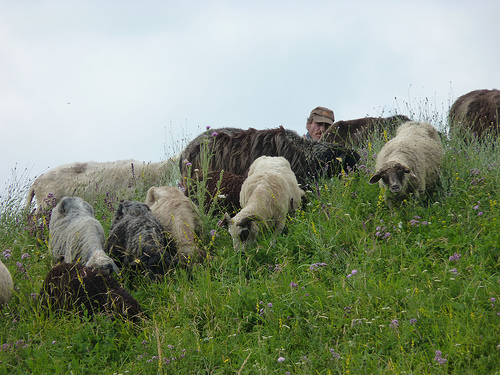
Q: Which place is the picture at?
A: It is at the pasture.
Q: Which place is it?
A: It is a pasture.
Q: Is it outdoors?
A: Yes, it is outdoors.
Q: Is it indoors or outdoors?
A: It is outdoors.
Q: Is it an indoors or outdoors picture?
A: It is outdoors.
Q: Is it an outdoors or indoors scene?
A: It is outdoors.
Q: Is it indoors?
A: No, it is outdoors.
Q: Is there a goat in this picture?
A: Yes, there is a goat.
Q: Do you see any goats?
A: Yes, there is a goat.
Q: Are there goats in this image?
A: Yes, there is a goat.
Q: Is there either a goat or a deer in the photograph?
A: Yes, there is a goat.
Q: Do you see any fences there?
A: No, there are no fences.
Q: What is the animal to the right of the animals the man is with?
A: The animal is a goat.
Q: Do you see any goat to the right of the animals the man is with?
A: Yes, there is a goat to the right of the animals.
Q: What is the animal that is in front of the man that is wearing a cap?
A: The animal is a goat.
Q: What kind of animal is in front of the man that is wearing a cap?
A: The animal is a goat.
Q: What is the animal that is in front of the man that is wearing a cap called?
A: The animal is a goat.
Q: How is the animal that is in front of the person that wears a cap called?
A: The animal is a goat.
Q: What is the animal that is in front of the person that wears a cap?
A: The animal is a goat.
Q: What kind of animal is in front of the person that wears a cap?
A: The animal is a goat.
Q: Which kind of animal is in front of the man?
A: The animal is a goat.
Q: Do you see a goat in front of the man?
A: Yes, there is a goat in front of the man.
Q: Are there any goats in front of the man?
A: Yes, there is a goat in front of the man.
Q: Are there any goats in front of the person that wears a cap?
A: Yes, there is a goat in front of the man.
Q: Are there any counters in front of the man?
A: No, there is a goat in front of the man.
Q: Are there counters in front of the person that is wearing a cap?
A: No, there is a goat in front of the man.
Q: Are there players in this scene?
A: No, there are no players.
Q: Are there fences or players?
A: No, there are no players or fences.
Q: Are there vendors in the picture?
A: No, there are no vendors.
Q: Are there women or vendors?
A: No, there are no vendors or women.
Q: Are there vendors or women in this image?
A: No, there are no vendors or women.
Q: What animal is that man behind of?
A: The man is behind the goat.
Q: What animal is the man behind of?
A: The man is behind the goat.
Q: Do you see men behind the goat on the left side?
A: Yes, there is a man behind the goat.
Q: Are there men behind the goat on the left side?
A: Yes, there is a man behind the goat.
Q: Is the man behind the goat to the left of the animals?
A: Yes, the man is behind the goat.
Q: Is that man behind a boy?
A: No, the man is behind the goat.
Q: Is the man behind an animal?
A: Yes, the man is behind an animal.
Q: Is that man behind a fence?
A: No, the man is behind an animal.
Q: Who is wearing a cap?
A: The man is wearing a cap.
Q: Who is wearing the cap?
A: The man is wearing a cap.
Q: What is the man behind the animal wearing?
A: The man is wearing a cap.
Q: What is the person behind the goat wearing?
A: The man is wearing a cap.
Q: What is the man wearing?
A: The man is wearing a cap.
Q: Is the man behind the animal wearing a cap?
A: Yes, the man is wearing a cap.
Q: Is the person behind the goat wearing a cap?
A: Yes, the man is wearing a cap.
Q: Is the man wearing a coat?
A: No, the man is wearing a cap.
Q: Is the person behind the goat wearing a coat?
A: No, the man is wearing a cap.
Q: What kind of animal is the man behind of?
A: The man is behind the goat.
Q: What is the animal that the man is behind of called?
A: The animal is a goat.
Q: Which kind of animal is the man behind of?
A: The man is behind the goat.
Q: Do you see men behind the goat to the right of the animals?
A: Yes, there is a man behind the goat.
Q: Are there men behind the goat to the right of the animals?
A: Yes, there is a man behind the goat.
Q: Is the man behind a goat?
A: Yes, the man is behind a goat.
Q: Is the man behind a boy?
A: No, the man is behind a goat.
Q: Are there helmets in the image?
A: No, there are no helmets.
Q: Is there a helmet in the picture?
A: No, there are no helmets.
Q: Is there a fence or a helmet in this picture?
A: No, there are no helmets or fences.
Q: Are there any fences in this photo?
A: No, there are no fences.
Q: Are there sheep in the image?
A: Yes, there is a sheep.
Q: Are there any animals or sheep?
A: Yes, there is a sheep.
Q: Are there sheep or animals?
A: Yes, there is a sheep.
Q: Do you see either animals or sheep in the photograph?
A: Yes, there is a sheep.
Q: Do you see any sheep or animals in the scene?
A: Yes, there is a sheep.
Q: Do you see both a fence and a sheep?
A: No, there is a sheep but no fences.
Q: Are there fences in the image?
A: No, there are no fences.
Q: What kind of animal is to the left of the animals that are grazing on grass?
A: The animal is a sheep.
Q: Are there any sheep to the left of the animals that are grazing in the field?
A: Yes, there is a sheep to the left of the animals.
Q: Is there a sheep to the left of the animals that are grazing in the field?
A: Yes, there is a sheep to the left of the animals.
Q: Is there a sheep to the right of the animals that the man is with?
A: No, the sheep is to the left of the animals.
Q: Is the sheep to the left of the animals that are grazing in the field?
A: Yes, the sheep is to the left of the animals.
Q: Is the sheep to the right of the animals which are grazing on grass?
A: No, the sheep is to the left of the animals.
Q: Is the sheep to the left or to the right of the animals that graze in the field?
A: The sheep is to the left of the animals.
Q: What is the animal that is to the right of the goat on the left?
A: The animal is a sheep.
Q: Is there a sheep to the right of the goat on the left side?
A: Yes, there is a sheep to the right of the goat.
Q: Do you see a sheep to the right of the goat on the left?
A: Yes, there is a sheep to the right of the goat.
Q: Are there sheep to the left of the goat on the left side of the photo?
A: No, the sheep is to the right of the goat.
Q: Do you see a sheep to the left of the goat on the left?
A: No, the sheep is to the right of the goat.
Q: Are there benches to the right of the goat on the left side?
A: No, there is a sheep to the right of the goat.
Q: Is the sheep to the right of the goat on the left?
A: Yes, the sheep is to the right of the goat.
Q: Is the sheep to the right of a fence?
A: No, the sheep is to the right of the goat.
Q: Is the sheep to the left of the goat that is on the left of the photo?
A: No, the sheep is to the right of the goat.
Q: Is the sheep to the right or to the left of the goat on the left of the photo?
A: The sheep is to the right of the goat.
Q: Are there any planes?
A: No, there are no planes.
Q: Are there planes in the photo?
A: No, there are no planes.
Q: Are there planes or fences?
A: No, there are no planes or fences.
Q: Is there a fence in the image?
A: No, there are no fences.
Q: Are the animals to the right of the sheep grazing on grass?
A: Yes, the animals are grazing on grass.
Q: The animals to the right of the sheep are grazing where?
A: The animals are grazing in the field.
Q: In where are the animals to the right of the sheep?
A: The animals are grazing in the field.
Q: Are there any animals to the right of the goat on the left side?
A: Yes, there are animals to the right of the goat.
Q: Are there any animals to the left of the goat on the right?
A: Yes, there are animals to the left of the goat.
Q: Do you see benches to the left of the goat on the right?
A: No, there are animals to the left of the goat.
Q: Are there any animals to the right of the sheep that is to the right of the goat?
A: Yes, there are animals to the right of the sheep.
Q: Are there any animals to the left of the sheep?
A: No, the animals are to the right of the sheep.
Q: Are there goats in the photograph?
A: Yes, there is a goat.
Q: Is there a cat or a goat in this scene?
A: Yes, there is a goat.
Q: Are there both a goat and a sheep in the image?
A: Yes, there are both a goat and a sheep.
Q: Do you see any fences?
A: No, there are no fences.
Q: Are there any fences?
A: No, there are no fences.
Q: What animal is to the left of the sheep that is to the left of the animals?
A: The animal is a goat.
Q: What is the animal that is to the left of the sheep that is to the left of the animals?
A: The animal is a goat.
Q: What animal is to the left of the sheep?
A: The animal is a goat.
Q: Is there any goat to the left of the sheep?
A: Yes, there is a goat to the left of the sheep.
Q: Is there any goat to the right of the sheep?
A: No, the goat is to the left of the sheep.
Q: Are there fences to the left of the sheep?
A: No, there is a goat to the left of the sheep.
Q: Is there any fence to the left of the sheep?
A: No, there is a goat to the left of the sheep.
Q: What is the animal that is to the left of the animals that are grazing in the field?
A: The animal is a goat.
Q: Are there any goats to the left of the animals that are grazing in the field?
A: Yes, there is a goat to the left of the animals.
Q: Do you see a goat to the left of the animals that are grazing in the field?
A: Yes, there is a goat to the left of the animals.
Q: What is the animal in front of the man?
A: The animal is a goat.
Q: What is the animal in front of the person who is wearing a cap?
A: The animal is a goat.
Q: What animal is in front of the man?
A: The animal is a goat.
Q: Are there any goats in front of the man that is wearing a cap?
A: Yes, there is a goat in front of the man.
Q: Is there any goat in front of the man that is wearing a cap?
A: Yes, there is a goat in front of the man.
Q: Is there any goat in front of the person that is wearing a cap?
A: Yes, there is a goat in front of the man.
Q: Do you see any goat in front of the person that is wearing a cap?
A: Yes, there is a goat in front of the man.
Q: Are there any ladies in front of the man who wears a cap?
A: No, there is a goat in front of the man.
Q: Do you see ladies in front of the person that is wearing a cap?
A: No, there is a goat in front of the man.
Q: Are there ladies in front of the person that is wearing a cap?
A: No, there is a goat in front of the man.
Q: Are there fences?
A: No, there are no fences.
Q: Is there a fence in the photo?
A: No, there are no fences.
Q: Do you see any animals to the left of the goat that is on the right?
A: Yes, there is an animal to the left of the goat.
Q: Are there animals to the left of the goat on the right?
A: Yes, there is an animal to the left of the goat.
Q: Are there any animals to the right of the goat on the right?
A: No, the animal is to the left of the goat.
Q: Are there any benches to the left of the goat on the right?
A: No, there is an animal to the left of the goat.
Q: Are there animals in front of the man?
A: Yes, there is an animal in front of the man.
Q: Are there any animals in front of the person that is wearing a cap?
A: Yes, there is an animal in front of the man.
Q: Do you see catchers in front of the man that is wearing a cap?
A: No, there is an animal in front of the man.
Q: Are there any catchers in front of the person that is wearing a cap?
A: No, there is an animal in front of the man.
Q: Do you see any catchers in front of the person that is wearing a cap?
A: No, there is an animal in front of the man.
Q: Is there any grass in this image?
A: Yes, there is grass.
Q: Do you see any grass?
A: Yes, there is grass.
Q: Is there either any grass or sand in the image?
A: Yes, there is grass.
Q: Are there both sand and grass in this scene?
A: No, there is grass but no sand.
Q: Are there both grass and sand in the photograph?
A: No, there is grass but no sand.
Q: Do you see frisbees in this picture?
A: No, there are no frisbees.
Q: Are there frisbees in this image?
A: No, there are no frisbees.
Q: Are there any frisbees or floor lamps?
A: No, there are no frisbees or floor lamps.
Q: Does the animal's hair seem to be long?
A: Yes, the hair is long.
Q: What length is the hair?
A: The hair is long.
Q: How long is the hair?
A: The hair is long.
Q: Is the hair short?
A: No, the hair is long.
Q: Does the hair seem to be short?
A: No, the hair is long.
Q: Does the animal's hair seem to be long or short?
A: The hair is long.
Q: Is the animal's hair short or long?
A: The hair is long.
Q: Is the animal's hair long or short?
A: The hair is long.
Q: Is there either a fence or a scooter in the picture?
A: No, there are no fences or scooters.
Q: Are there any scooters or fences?
A: No, there are no fences or scooters.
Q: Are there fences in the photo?
A: No, there are no fences.